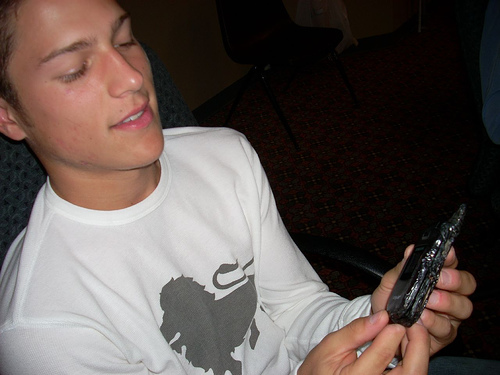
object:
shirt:
[0, 125, 398, 373]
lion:
[159, 257, 266, 374]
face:
[35, 10, 163, 153]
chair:
[214, 0, 362, 148]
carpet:
[199, 25, 498, 360]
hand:
[298, 308, 431, 375]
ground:
[199, 0, 499, 362]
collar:
[44, 151, 170, 225]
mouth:
[108, 97, 154, 131]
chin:
[130, 127, 165, 168]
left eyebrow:
[110, 10, 133, 41]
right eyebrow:
[35, 35, 93, 68]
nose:
[105, 45, 145, 99]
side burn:
[1, 84, 36, 129]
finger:
[339, 323, 406, 374]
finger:
[435, 266, 477, 296]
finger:
[425, 287, 474, 320]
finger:
[420, 306, 456, 342]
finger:
[388, 317, 432, 375]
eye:
[50, 60, 87, 81]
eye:
[116, 35, 136, 48]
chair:
[1, 62, 396, 312]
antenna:
[439, 199, 470, 244]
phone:
[387, 207, 464, 325]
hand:
[365, 242, 478, 357]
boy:
[1, 2, 476, 372]